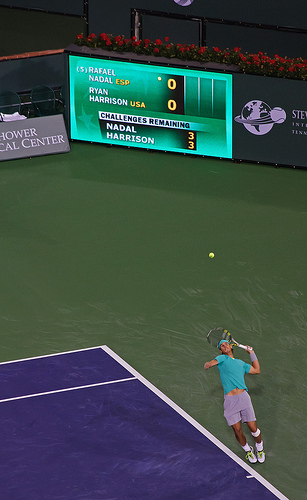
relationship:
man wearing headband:
[204, 339, 266, 463] [217, 339, 229, 347]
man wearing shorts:
[204, 339, 266, 463] [223, 391, 256, 425]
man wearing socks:
[204, 339, 266, 463] [242, 441, 263, 452]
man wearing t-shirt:
[204, 339, 266, 463] [215, 355, 251, 393]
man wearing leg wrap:
[204, 339, 266, 463] [251, 428, 261, 438]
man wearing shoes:
[204, 339, 266, 463] [247, 449, 266, 463]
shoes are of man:
[247, 449, 266, 463] [204, 339, 266, 463]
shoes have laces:
[247, 449, 266, 463] [247, 452, 264, 458]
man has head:
[204, 339, 266, 463] [218, 340, 233, 354]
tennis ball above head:
[208, 252, 214, 257] [218, 340, 233, 354]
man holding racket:
[204, 339, 266, 463] [207, 326, 253, 351]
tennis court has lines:
[1, 345, 288, 500] [0, 345, 137, 401]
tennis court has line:
[1, 345, 288, 500] [138, 376, 287, 500]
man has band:
[204, 339, 266, 463] [247, 350, 257, 364]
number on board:
[167, 79, 176, 89] [68, 55, 234, 160]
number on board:
[167, 100, 175, 111] [68, 55, 234, 160]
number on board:
[189, 133, 194, 141] [68, 55, 234, 160]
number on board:
[187, 142, 195, 150] [68, 55, 234, 160]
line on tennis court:
[1, 378, 140, 403] [1, 345, 288, 500]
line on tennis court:
[138, 376, 287, 500] [1, 345, 288, 500]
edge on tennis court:
[1, 344, 139, 380] [1, 345, 288, 500]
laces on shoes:
[247, 452, 264, 458] [247, 449, 266, 463]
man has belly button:
[204, 339, 266, 463] [230, 388, 241, 394]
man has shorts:
[204, 339, 266, 463] [223, 391, 256, 425]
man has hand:
[204, 339, 266, 463] [245, 346, 253, 353]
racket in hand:
[207, 326, 253, 351] [245, 346, 253, 353]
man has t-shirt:
[204, 339, 266, 463] [215, 355, 251, 393]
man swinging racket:
[204, 339, 266, 463] [207, 326, 253, 351]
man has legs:
[204, 339, 266, 463] [232, 421, 261, 446]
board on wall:
[68, 55, 234, 160] [65, 50, 306, 168]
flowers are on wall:
[76, 32, 307, 79] [65, 50, 306, 168]